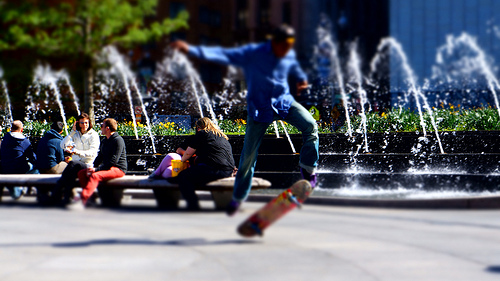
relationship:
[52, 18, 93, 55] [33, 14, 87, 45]
leaves on tree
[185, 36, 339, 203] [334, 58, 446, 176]
skateboarder in air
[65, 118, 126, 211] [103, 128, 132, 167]
man wearing top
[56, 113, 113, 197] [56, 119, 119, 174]
woman wearing jacket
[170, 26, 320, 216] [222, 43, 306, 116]
skateboarder wearing shirt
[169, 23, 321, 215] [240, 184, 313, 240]
boy on skateboard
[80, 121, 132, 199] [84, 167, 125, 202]
man wearing pants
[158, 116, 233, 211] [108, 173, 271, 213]
woman on bench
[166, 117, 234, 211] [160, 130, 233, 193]
woman wearing outfit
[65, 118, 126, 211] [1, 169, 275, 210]
man on bench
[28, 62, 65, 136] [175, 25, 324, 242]
fountain by skate boarder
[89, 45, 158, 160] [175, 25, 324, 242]
fountain by skate boarder